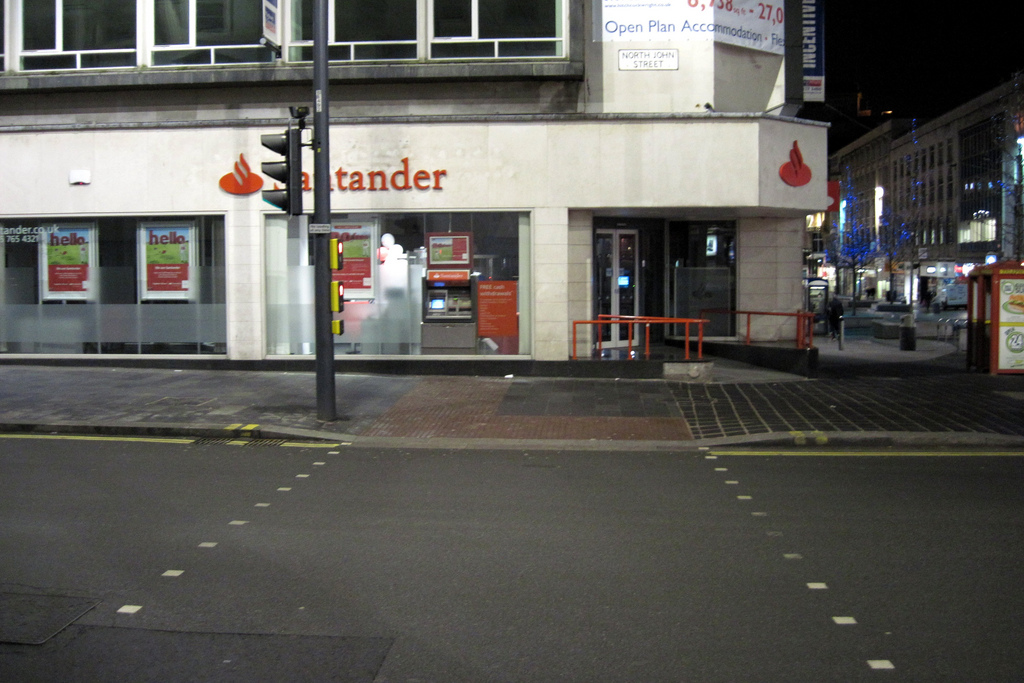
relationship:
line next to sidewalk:
[1, 427, 337, 449] [1, 360, 1023, 443]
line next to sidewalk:
[703, 440, 1023, 464] [1, 360, 1023, 443]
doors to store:
[590, 225, 651, 355] [2, 3, 837, 375]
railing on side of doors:
[570, 314, 710, 361] [592, 229, 639, 351]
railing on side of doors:
[713, 294, 826, 357] [592, 229, 639, 351]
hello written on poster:
[145, 219, 189, 246] [139, 215, 194, 300]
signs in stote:
[20, 220, 209, 309] [2, 108, 839, 342]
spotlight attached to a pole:
[255, 113, 316, 250] [300, 22, 342, 386]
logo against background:
[231, 163, 452, 196] [170, 100, 659, 280]